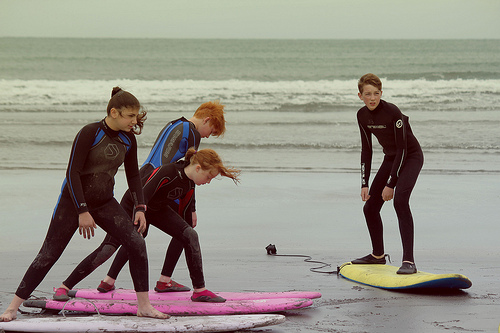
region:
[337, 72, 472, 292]
a boy on a yellow surfboard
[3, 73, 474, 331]
four kids at the beach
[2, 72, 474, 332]
four kids standing on surfboards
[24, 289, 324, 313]
two pink surfboards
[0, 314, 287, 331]
a white surfboard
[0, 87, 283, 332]
a girl on a white surfboard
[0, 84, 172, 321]
a barefoot girl on a surfboard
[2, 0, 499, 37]
the sky above the ocean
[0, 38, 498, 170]
the ocean behind the kids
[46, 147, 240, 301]
a girl with red hair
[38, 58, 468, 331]
young kids learning how to surf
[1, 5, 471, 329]
kids learning to surf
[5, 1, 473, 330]
people learning to surf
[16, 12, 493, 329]
boys and girls learning to surf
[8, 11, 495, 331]
they are learning to surf at the beach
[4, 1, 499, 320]
they are all wearing wetsuits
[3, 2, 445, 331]
they all have black wet suits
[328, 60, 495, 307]
he is standing on a yellow board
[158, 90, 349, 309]
they are standing on pink boards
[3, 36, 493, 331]
the wind is blowing their hair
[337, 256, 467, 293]
surf board in yellow on top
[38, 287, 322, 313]
two pink surf boards side by side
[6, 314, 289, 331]
one white surf board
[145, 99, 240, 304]
two children with red hair on surf boards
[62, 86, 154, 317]
one girl with a ponytail on a surfboard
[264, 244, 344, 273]
ankle board attached to the back of board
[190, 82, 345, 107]
white waves in the back ground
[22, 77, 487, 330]
children standing on surfboards on the beach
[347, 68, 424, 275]
boy wearing black and white on a board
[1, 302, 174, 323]
girl is not wearing shoes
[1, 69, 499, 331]
kids learning how to surf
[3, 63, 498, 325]
kids doing surfing lessons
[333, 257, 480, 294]
yellow and blue surf board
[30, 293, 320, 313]
women's pink surf board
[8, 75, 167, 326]
girl learning how to surf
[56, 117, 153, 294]
black and blue wet suit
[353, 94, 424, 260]
black and white wet suit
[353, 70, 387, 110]
young boy with brown hair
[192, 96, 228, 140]
young boy with orange hair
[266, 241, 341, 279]
surf board safety leash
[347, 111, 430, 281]
the swimsuit is black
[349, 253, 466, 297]
the sufrboard is yellow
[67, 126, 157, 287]
the swimsuit is blue and black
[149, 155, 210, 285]
the swimsuit is red and black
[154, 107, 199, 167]
the swimsuit is blue and black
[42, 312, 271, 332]
the surfboard is white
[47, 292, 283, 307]
the surfboard is orange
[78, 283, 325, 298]
the surfboard is orange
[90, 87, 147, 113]
the hair is blacck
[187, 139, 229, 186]
the hair is brown